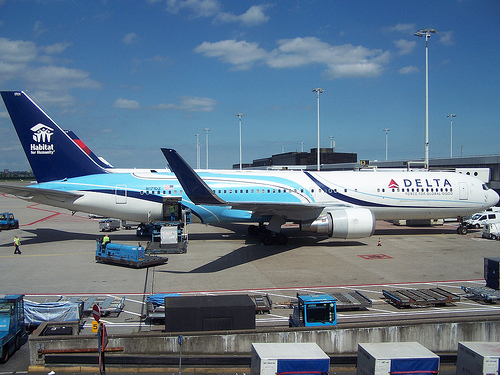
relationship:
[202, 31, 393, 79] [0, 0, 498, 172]
clouds in sky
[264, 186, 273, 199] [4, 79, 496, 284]
window on airplane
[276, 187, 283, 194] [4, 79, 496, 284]
window on airplane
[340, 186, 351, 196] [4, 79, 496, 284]
window on airplane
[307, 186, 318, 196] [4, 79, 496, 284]
window on airplane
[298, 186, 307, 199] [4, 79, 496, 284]
window on airplane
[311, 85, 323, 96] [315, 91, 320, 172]
light on pole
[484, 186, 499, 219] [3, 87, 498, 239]
nose of plane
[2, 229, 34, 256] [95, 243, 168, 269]
person on equipment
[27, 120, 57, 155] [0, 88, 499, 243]
sign on airplane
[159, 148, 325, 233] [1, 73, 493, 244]
wing on airplane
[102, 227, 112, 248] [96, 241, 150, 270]
worker operates equipment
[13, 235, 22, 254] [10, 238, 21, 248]
person wears shirt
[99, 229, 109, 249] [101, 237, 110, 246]
employee wears shirt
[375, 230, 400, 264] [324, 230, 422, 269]
cone on tarmac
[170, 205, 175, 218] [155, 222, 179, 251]
people loading supplies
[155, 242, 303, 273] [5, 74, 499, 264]
wing's shadow of airplane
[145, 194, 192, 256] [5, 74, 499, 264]
ramp of airplane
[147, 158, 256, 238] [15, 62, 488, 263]
wing of a plane